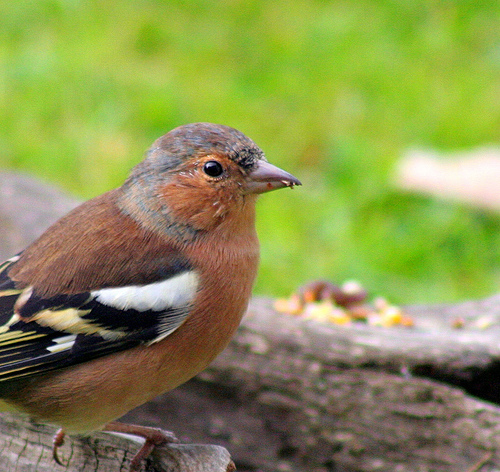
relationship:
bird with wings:
[0, 121, 301, 469] [38, 259, 201, 384]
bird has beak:
[0, 121, 301, 469] [251, 156, 303, 195]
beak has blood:
[251, 156, 303, 195] [267, 183, 273, 191]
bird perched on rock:
[0, 121, 301, 469] [2, 414, 233, 470]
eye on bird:
[201, 157, 223, 178] [0, 121, 301, 469]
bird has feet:
[0, 121, 301, 469] [51, 423, 176, 470]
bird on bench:
[0, 121, 301, 469] [1, 406, 237, 470]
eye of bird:
[203, 160, 223, 178] [0, 121, 301, 469]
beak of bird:
[251, 155, 301, 196] [0, 121, 301, 469]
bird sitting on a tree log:
[0, 121, 301, 469] [2, 167, 499, 468]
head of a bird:
[140, 117, 301, 237] [0, 121, 301, 469]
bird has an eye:
[0, 121, 301, 469] [204, 157, 222, 177]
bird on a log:
[0, 121, 301, 469] [2, 172, 496, 470]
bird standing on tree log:
[0, 121, 301, 469] [2, 167, 499, 468]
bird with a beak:
[0, 121, 301, 469] [247, 151, 300, 195]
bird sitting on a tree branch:
[0, 121, 301, 469] [2, 170, 498, 470]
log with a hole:
[2, 172, 496, 470] [331, 353, 499, 413]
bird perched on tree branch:
[0, 121, 301, 469] [2, 170, 498, 470]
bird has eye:
[0, 121, 301, 469] [202, 159, 220, 179]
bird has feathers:
[0, 121, 301, 469] [0, 266, 199, 385]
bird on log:
[0, 121, 301, 469] [2, 172, 496, 470]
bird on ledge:
[0, 121, 301, 469] [0, 170, 496, 470]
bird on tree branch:
[0, 121, 301, 469] [2, 170, 498, 470]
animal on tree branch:
[2, 117, 303, 466] [2, 170, 498, 470]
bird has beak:
[0, 121, 301, 469] [250, 160, 300, 190]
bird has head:
[0, 121, 301, 469] [151, 122, 305, 227]